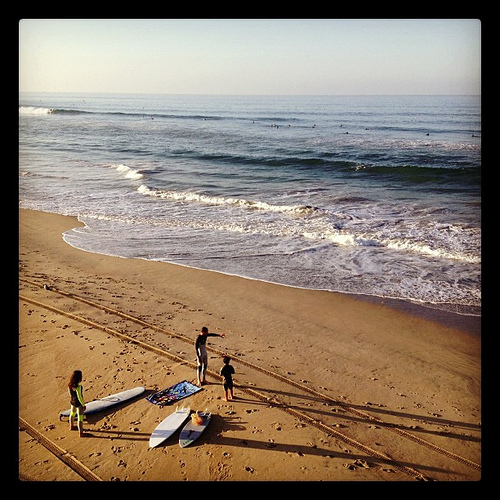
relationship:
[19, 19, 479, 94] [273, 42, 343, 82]
sky with clouds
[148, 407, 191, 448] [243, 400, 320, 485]
surfboard kept in sand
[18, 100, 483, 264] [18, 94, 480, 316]
waves in water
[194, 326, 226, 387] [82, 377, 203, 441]
man standing near surfboard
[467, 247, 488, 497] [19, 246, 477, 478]
sand with footprints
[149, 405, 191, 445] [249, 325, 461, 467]
surfboard in sand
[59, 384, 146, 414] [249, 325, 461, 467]
surfboard in sand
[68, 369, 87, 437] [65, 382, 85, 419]
person in wetsuit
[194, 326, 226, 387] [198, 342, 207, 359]
man in clothes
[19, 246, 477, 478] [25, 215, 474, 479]
footprints in sand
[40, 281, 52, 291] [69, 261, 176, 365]
bird in sand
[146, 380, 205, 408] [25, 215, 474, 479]
beach towel in sand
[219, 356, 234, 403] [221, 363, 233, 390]
boy wearing clothes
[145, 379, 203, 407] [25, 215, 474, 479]
beach towel laid out sand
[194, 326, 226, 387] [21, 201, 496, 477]
man at beach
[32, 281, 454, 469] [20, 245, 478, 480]
marks in sand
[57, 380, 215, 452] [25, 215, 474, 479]
surfboards on sand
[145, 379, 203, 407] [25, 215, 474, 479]
beach towel on sand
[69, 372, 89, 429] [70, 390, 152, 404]
person standing next to surfboard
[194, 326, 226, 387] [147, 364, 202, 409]
man standing next to towel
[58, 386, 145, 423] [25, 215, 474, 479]
surfboard on sand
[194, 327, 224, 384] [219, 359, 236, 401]
man talking to child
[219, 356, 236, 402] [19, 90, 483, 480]
boy on beach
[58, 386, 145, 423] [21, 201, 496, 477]
surfboard on beach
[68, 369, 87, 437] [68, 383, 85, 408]
person in clothes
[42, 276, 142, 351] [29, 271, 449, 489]
lines in sand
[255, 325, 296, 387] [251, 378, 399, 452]
prints in sand